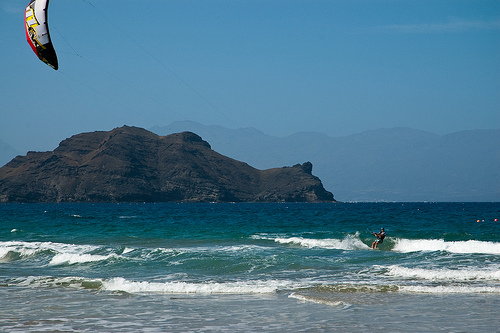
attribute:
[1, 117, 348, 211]
mountain — in the back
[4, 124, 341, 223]
mountain — big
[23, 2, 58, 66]
parafoil — multicolored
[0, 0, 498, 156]
sky — blue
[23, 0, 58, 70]
parasail — colored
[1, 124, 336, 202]
mountain — rocky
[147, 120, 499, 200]
mountains — hazy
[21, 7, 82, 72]
object — flying in air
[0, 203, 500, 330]
water — flow, surface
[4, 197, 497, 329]
ocean — rough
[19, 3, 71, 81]
object — in air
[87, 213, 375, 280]
water — a flow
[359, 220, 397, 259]
man/water — jumping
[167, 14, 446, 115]
sky — blue, daytime